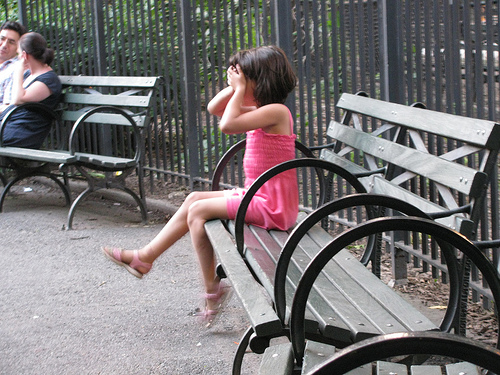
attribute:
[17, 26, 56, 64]
hair — pulled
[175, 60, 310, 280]
girl — young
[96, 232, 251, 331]
sandals — pink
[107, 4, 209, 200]
fence — black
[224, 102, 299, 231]
frock — pink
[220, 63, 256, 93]
eyes — closed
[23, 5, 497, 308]
fencing — steel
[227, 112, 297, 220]
dress — pink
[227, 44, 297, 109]
hair — short, black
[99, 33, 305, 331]
girl — young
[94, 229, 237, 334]
shoes — pink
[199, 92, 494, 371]
bench — wood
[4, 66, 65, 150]
top — dark